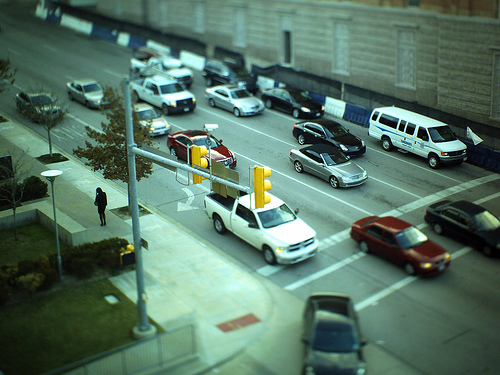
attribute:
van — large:
[361, 101, 475, 175]